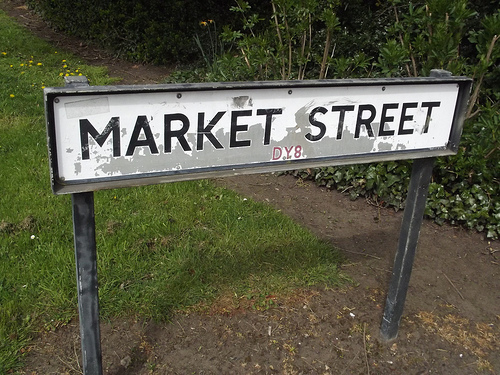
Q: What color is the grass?
A: Green.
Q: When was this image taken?
A: Daytime.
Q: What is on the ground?
A: Grass.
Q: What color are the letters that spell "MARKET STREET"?
A: Black.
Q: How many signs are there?
A: One.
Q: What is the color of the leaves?
A: Green.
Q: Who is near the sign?
A: No one.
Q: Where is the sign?
A: Market Street.